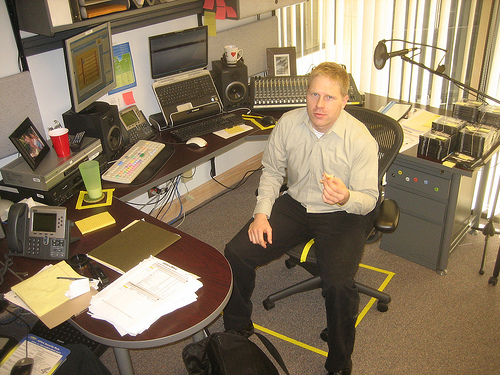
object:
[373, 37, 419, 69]
microphone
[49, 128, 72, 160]
cup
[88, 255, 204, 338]
papers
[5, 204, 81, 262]
telephone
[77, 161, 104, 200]
cup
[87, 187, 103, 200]
liquid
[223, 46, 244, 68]
mug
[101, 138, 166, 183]
keyboard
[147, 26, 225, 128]
laptop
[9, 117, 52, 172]
frame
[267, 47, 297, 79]
frame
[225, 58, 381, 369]
man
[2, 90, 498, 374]
desk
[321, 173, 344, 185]
food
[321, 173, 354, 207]
hand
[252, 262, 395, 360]
lines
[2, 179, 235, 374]
table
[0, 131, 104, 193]
device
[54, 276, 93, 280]
pen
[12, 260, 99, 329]
pad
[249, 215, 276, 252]
hand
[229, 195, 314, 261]
thigh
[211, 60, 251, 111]
speaker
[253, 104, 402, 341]
chair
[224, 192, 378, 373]
pants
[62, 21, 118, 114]
monitor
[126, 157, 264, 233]
cords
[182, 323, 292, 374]
case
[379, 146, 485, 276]
cabinet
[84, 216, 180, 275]
folder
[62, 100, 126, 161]
speaker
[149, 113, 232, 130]
stand